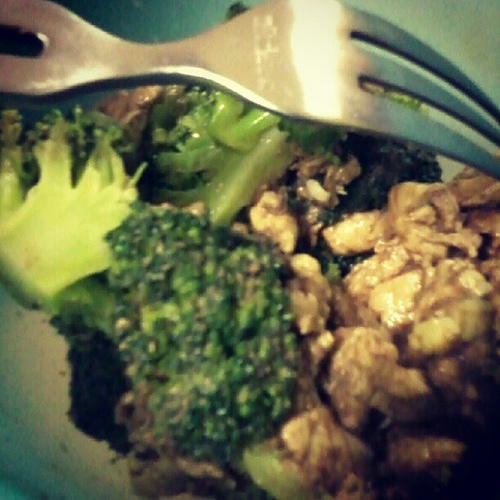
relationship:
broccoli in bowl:
[14, 209, 116, 245] [134, 16, 168, 31]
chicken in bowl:
[359, 270, 397, 386] [134, 16, 168, 31]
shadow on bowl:
[9, 40, 30, 52] [134, 16, 168, 31]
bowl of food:
[134, 16, 168, 31] [138, 164, 300, 278]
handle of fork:
[12, 16, 137, 83] [155, 51, 415, 125]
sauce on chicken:
[294, 277, 326, 297] [359, 270, 397, 386]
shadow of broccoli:
[9, 40, 30, 52] [14, 209, 116, 245]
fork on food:
[155, 51, 415, 125] [138, 164, 300, 278]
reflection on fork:
[307, 107, 351, 108] [155, 51, 415, 125]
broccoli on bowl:
[14, 209, 116, 245] [134, 16, 168, 31]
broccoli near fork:
[14, 209, 116, 245] [155, 51, 415, 125]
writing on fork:
[262, 23, 286, 87] [155, 51, 415, 125]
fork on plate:
[155, 51, 415, 125] [142, 24, 157, 31]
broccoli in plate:
[14, 209, 116, 245] [142, 24, 157, 31]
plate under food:
[142, 24, 157, 31] [138, 164, 300, 278]